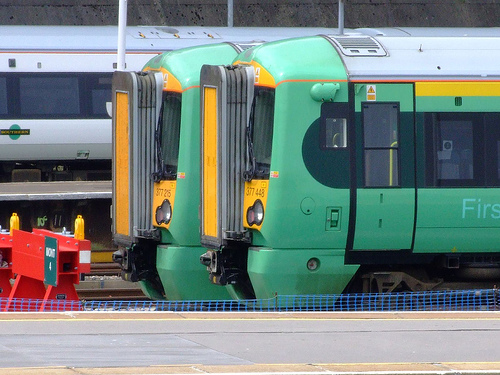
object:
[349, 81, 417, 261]
door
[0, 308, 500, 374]
road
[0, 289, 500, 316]
netting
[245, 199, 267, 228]
headlight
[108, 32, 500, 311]
train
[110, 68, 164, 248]
door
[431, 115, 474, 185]
window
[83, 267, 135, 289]
gravel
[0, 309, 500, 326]
tracks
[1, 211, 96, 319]
device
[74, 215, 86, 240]
light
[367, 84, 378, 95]
sticker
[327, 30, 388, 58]
vent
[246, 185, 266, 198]
numbers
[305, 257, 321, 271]
light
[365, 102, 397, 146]
window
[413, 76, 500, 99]
stripe